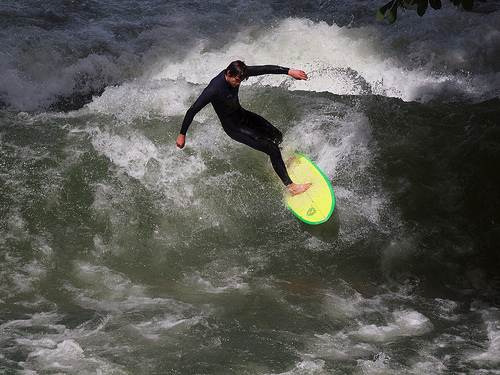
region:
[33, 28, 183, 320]
crashing waves in an ocean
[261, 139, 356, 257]
green and yellow surf board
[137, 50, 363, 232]
surfer wearing a full black wet suit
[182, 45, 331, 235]
surfer wearing a black wet suit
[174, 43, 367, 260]
surfer surfing on a green and yellow surfboard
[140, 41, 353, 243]
man balancing on a surf board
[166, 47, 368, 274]
man riding the waves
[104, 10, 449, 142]
vicous waves crashing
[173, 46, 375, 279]
man leaning while on a surf board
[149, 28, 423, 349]
man in black riding waves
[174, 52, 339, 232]
surfer catching a medium wave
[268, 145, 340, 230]
yellow and green surfboard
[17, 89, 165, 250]
medium sized ocean wave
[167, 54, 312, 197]
man in a wet suit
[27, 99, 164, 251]
frothy cap of a wave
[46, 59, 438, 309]
surfer riding down curl of wave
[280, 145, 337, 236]
foot of surfer planted firmly on surfboard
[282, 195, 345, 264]
yellow and green surfboard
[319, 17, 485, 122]
raging ocean current with foamy cap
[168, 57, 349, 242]
surfer in wetsuit on surfboard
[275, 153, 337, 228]
a lime green surf board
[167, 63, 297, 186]
a dark black wetsuit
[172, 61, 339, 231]
a surfer on a yellow surfboard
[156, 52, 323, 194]
a surfer with outstretched arms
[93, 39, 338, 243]
a surfer riding the waves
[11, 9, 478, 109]
foamy waves in the ocean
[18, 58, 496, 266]
a surfer on a tall wave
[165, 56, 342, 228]
a surfer in a black wetsuit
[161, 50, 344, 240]
a surfer riding a wave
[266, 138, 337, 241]
the surfboard is yellow with green trim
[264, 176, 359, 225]
the surfboard is yellow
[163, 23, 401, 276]
the man is surfing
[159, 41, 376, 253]
the man is wearing a wet suit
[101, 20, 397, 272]
the man is wearing a black wet suit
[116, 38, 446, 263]
the man is surfing on a wave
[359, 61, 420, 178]
the water is dark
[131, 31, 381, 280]
the man has no shoes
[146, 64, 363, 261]
the man is participating in a sport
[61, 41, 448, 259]
the man is mid pose